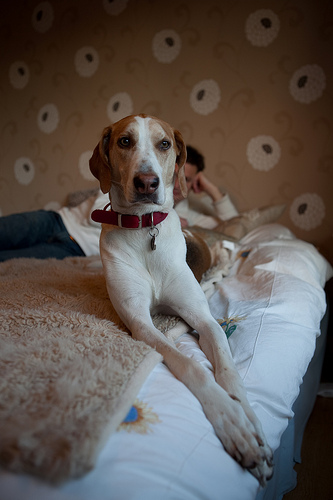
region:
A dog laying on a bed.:
[83, 110, 213, 323]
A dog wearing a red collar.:
[86, 122, 176, 258]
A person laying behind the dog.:
[184, 147, 236, 214]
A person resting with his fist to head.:
[176, 154, 218, 206]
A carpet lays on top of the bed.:
[14, 299, 169, 391]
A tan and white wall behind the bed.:
[198, 84, 314, 212]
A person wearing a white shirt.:
[68, 198, 91, 246]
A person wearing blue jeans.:
[3, 213, 76, 261]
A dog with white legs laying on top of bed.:
[125, 274, 265, 458]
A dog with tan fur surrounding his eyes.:
[114, 126, 188, 161]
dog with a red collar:
[66, 98, 277, 489]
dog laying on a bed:
[66, 104, 310, 483]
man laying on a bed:
[4, 146, 241, 248]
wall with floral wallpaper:
[4, 1, 322, 231]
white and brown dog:
[76, 107, 276, 497]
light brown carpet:
[5, 247, 178, 489]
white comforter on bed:
[105, 234, 331, 498]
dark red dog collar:
[90, 205, 188, 250]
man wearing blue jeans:
[4, 146, 265, 280]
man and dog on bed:
[2, 131, 325, 491]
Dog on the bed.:
[86, 109, 279, 489]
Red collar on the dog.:
[83, 114, 182, 239]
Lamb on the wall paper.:
[244, 131, 283, 173]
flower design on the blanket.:
[116, 395, 159, 435]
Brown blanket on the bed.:
[0, 253, 211, 489]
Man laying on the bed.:
[2, 133, 236, 260]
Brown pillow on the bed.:
[216, 199, 288, 239]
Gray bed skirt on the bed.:
[254, 301, 331, 499]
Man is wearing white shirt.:
[56, 140, 237, 262]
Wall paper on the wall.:
[1, 0, 329, 259]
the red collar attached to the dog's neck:
[87, 201, 171, 230]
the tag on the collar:
[144, 223, 158, 250]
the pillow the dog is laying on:
[5, 258, 197, 465]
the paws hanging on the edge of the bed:
[214, 385, 275, 485]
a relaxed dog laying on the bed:
[85, 113, 268, 482]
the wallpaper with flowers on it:
[3, 3, 330, 218]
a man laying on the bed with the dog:
[2, 146, 236, 258]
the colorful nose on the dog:
[131, 173, 159, 195]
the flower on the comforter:
[113, 392, 165, 441]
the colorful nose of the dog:
[133, 173, 162, 194]